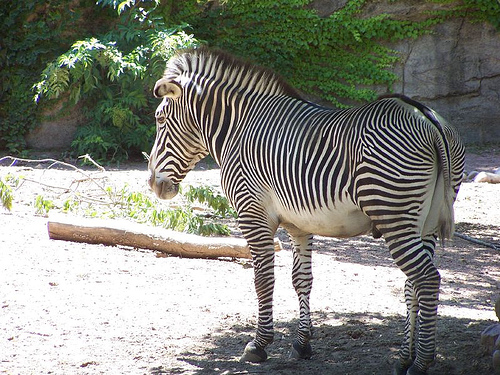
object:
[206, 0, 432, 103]
vine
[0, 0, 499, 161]
wall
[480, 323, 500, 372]
rocks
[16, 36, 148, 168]
plant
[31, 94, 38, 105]
leaves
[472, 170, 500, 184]
rocks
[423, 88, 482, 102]
crack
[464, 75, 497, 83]
crack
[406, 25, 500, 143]
rock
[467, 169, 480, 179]
rocks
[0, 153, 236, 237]
leafy branch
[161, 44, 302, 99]
mane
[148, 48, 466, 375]
zebra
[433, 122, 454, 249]
tail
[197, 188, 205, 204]
leaves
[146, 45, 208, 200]
head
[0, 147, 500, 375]
ground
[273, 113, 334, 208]
stripes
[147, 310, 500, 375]
shadow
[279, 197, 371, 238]
belly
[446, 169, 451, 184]
edge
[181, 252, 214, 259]
edge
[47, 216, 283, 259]
log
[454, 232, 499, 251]
stick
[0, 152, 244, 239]
tree limb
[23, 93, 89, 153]
rock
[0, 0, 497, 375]
background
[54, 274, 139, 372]
part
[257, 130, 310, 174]
part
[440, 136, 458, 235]
part